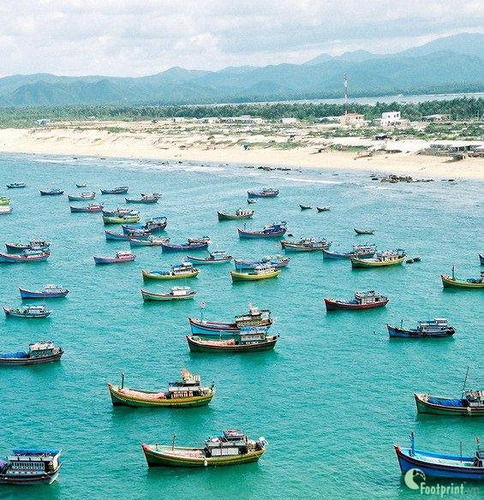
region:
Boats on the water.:
[84, 155, 371, 496]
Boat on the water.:
[95, 341, 247, 413]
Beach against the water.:
[209, 111, 360, 201]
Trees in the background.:
[137, 77, 323, 136]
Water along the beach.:
[155, 151, 354, 217]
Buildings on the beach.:
[234, 64, 441, 169]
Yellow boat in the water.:
[98, 362, 262, 412]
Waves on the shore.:
[115, 142, 273, 215]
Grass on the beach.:
[117, 122, 332, 154]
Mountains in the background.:
[28, 62, 299, 113]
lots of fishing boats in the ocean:
[10, 159, 475, 489]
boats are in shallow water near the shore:
[3, 184, 474, 483]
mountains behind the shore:
[0, 33, 480, 100]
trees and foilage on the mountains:
[0, 55, 478, 98]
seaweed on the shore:
[35, 128, 398, 154]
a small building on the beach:
[431, 136, 479, 162]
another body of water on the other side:
[188, 93, 472, 98]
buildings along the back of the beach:
[196, 111, 445, 129]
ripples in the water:
[6, 161, 470, 493]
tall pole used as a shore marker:
[338, 73, 351, 122]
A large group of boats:
[5, 154, 482, 483]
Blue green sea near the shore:
[5, 159, 477, 495]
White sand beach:
[4, 113, 481, 184]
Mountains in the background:
[4, 33, 477, 109]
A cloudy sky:
[2, 4, 479, 79]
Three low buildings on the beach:
[334, 108, 455, 127]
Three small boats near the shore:
[295, 200, 384, 237]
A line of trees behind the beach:
[7, 98, 479, 124]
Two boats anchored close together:
[178, 306, 291, 362]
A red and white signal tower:
[336, 68, 356, 135]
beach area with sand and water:
[2, 119, 477, 485]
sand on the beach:
[5, 96, 477, 175]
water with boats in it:
[1, 162, 475, 489]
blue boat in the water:
[382, 439, 482, 481]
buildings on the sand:
[266, 106, 439, 119]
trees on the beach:
[207, 99, 482, 115]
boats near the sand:
[32, 173, 372, 222]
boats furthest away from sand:
[95, 368, 264, 497]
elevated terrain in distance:
[3, 35, 467, 104]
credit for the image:
[390, 466, 483, 498]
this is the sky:
[85, 11, 293, 58]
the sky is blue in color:
[243, 36, 290, 47]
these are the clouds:
[94, 37, 152, 64]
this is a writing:
[417, 482, 469, 498]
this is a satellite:
[338, 61, 361, 119]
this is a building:
[380, 108, 406, 121]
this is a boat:
[145, 440, 261, 464]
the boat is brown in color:
[138, 399, 164, 410]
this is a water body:
[281, 363, 352, 444]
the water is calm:
[289, 368, 353, 443]